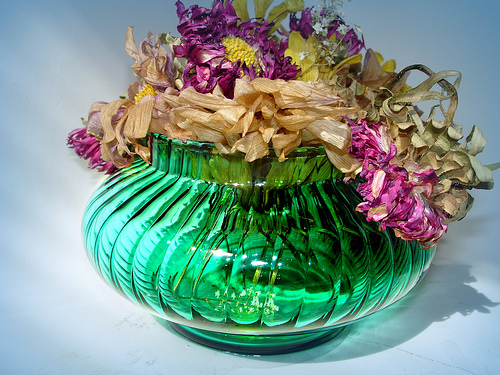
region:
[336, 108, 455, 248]
a purple flower in a vase.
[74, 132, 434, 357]
a green shiney vase.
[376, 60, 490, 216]
dry plants in a vase.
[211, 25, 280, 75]
green flowers in a vase.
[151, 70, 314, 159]
A pile of brown leaves.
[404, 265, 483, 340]
A shadow cast on a white surface.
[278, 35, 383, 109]
a section of dry plants.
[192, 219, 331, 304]
a shiney green surface.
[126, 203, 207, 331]
the side of a vase.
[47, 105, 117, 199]
a purple flower in a vase.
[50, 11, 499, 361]
a beautiful small pot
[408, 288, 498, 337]
shadow of the pot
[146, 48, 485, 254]
flowers in the pot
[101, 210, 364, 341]
a green color pot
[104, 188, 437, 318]
a series of design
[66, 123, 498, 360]
a cool looking pot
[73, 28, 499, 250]
a different type of colors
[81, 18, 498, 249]
a cute design on pot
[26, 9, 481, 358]
a pot placed in floor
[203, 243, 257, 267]
a white marks on pot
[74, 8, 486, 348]
a small green vase holds some flowers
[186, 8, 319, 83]
the flowers are purple in color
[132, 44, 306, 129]
some of the flowers have died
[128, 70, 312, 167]
the dead flowers are turning brown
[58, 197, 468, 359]
the surface the vase is on is white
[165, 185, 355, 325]
some of the stems are visible through the vase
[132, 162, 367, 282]
the vase does not have a flat surface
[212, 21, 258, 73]
the center of the flower is yellow in color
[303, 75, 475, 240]
the flowers have wilted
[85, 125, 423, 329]
the vase is an emerald shade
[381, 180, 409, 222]
This section is purple.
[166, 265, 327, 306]
This vase is green.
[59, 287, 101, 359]
The table is light blue.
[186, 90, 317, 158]
Beige colored leaves protrude from the pot.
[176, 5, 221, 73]
Purple flowers at the top.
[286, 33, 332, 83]
A yellow flower at the top.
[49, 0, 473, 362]
A small vase with flowers.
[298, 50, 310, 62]
A white stigma at the center of the flower.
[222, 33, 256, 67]
Yellow bits in the flowers.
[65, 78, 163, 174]
Yellow, beige and purple flowers meet here.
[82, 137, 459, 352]
The green vase the flowers are in.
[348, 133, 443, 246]
The purple flowers on the right.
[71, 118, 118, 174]
The purple flower on the left.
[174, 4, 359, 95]
The purple flowers in the middle.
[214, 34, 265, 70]
The yellow center of the flower in the middle.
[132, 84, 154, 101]
The yellow center of the flower on the left.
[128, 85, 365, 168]
The brown decoration in the middle.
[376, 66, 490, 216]
The brown decoration on the right.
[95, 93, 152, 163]
The brown decoration on the left.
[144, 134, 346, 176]
The rim of the green vase.